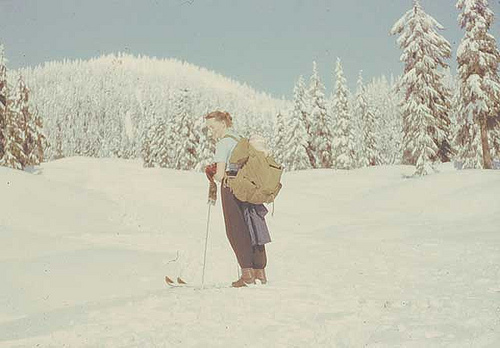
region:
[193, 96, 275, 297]
person with bookbag in snow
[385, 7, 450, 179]
snow covered evergreen tree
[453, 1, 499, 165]
snow covered evergreen tree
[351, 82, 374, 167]
snow covered evergreen tree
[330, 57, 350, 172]
snow covered evergreen tree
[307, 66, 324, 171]
snow covered evergreen tree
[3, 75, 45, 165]
snow covered evergreen tree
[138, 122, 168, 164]
snow covered evergreen tree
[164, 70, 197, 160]
snow covered evergreen tree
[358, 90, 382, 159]
snow covered evergreen tree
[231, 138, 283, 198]
a women carrying a bag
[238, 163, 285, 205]
the bag is brown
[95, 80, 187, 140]
the trees on the mountain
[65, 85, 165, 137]
the trees are covered in snow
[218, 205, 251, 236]
the women is wearing pants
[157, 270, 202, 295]
skiis are in the snow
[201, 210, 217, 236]
the womens is holding ski poles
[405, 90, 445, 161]
the trees have snow on them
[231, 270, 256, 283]
brown boots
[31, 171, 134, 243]
the snow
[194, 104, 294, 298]
woman standing in snow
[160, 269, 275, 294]
skies of woman standing in snow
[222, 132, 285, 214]
backpack of woman standing in snow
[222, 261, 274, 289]
ski boots of women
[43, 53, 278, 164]
tree and snow covered mountain in background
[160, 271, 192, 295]
tips of woman's skis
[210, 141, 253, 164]
light colored shirt woman is wearing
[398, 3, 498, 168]
two tall trees on the right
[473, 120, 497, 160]
tree trunk of furthest tree on right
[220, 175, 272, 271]
dark colored pants woman is wearing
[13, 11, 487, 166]
Trees covered with snow.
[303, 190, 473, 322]
White snow on the ground.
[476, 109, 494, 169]
Long brown tree trunk.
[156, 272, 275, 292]
Winter skis for skiing.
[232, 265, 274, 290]
Brown leather boots for protection.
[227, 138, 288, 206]
Army green backpack.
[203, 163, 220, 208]
Red and brown scarf.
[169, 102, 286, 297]
Lady standing in the snow.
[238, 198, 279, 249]
Gray jacket to keep out the cold.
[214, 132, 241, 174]
White short sleeve shirt.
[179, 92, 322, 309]
woman on the snow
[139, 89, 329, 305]
woman skiing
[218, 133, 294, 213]
large backpack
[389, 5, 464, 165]
skinny tree coverdin snow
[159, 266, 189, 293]
top of the skis are bent upward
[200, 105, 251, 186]
woman wearing a short slee shirt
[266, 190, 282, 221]
strap hanging down from the backpack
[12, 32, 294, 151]
hill covered in snowy trees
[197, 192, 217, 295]
skinny ski pole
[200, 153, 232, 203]
fabric hanging down from the arm